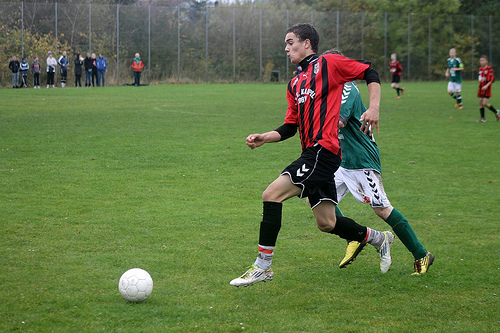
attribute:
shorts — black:
[293, 146, 343, 209]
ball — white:
[99, 270, 163, 299]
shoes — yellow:
[412, 253, 433, 276]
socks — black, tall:
[260, 197, 289, 254]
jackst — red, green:
[125, 43, 149, 91]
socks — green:
[387, 214, 438, 279]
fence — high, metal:
[154, 11, 243, 94]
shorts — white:
[346, 166, 399, 222]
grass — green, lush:
[24, 124, 173, 226]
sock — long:
[339, 214, 371, 252]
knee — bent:
[265, 188, 282, 209]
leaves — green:
[375, 15, 440, 62]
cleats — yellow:
[367, 224, 434, 286]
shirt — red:
[330, 60, 345, 80]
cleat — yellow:
[346, 243, 365, 269]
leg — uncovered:
[243, 162, 308, 297]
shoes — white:
[232, 261, 273, 297]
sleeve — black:
[351, 63, 380, 84]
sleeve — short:
[326, 51, 368, 83]